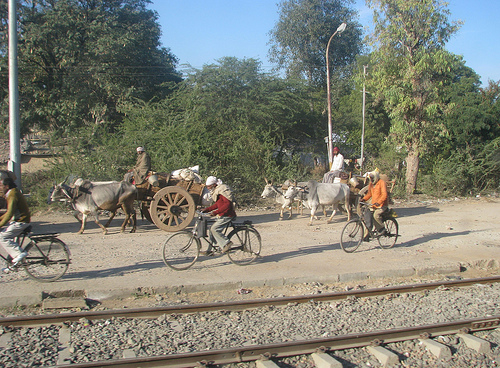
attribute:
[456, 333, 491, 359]
board — wooden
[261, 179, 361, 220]
ox — white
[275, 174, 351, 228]
ox — white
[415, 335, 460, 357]
board — wooden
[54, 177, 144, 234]
ox — white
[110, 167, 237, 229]
cart — brown